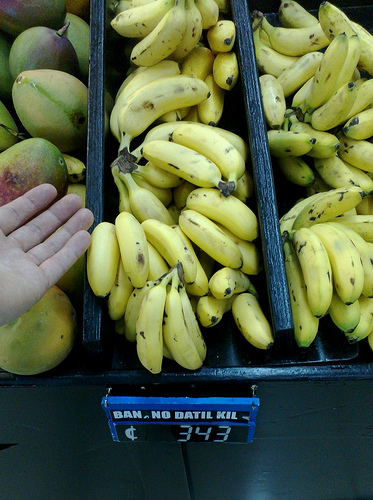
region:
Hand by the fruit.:
[6, 177, 155, 330]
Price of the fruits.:
[104, 373, 365, 475]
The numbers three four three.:
[177, 409, 278, 467]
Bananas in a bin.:
[96, 181, 271, 386]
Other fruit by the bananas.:
[17, 23, 108, 186]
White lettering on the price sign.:
[93, 390, 270, 465]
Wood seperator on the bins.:
[231, 18, 304, 317]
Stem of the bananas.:
[156, 265, 211, 301]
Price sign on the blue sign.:
[115, 406, 163, 461]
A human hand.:
[18, 184, 130, 330]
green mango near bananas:
[10, 68, 84, 149]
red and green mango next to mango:
[0, 135, 67, 202]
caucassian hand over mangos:
[0, 180, 90, 324]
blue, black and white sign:
[100, 384, 256, 447]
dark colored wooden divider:
[79, 0, 104, 363]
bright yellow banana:
[137, 139, 229, 188]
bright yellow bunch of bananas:
[289, 220, 367, 350]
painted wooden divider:
[230, 0, 289, 349]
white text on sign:
[109, 407, 235, 416]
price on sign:
[122, 423, 229, 441]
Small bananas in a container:
[85, 4, 372, 394]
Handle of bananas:
[102, 0, 226, 76]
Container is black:
[61, 4, 370, 387]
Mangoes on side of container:
[1, 9, 86, 376]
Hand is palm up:
[0, 177, 98, 336]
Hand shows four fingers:
[1, 175, 95, 340]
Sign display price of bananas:
[97, 393, 266, 452]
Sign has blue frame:
[89, 387, 263, 457]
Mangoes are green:
[2, 18, 87, 188]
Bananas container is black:
[68, 1, 370, 393]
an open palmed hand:
[0, 175, 100, 327]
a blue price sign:
[83, 392, 286, 461]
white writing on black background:
[98, 396, 255, 444]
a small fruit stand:
[10, 19, 356, 355]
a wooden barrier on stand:
[226, 42, 296, 309]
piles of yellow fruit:
[121, 101, 238, 340]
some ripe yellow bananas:
[292, 211, 368, 325]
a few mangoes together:
[11, 4, 70, 180]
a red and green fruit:
[4, 136, 72, 194]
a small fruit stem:
[55, 13, 75, 40]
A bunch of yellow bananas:
[106, 11, 344, 251]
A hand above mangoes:
[1, 133, 95, 371]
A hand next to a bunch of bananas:
[1, 162, 207, 375]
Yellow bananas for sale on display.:
[90, 3, 371, 450]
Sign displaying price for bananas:
[91, 215, 266, 455]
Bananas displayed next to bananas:
[4, 2, 250, 177]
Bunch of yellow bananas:
[124, 260, 203, 378]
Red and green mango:
[0, 134, 65, 181]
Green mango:
[11, 68, 89, 133]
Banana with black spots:
[278, 183, 357, 218]